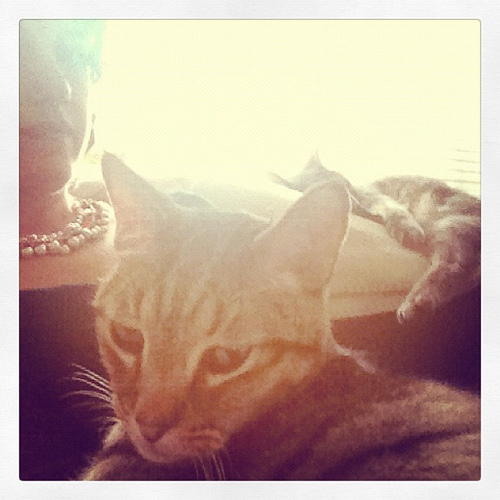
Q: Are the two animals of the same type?
A: Yes, all the animals are cats.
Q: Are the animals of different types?
A: No, all the animals are cats.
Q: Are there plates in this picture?
A: No, there are no plates.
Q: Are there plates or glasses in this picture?
A: No, there are no plates or glasses.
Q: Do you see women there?
A: Yes, there is a woman.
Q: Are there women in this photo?
A: Yes, there is a woman.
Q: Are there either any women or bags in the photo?
A: Yes, there is a woman.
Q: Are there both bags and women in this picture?
A: No, there is a woman but no bags.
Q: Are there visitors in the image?
A: No, there are no visitors.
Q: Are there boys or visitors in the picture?
A: No, there are no visitors or boys.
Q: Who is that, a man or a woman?
A: That is a woman.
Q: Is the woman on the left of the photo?
A: Yes, the woman is on the left of the image.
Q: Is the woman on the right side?
A: No, the woman is on the left of the image.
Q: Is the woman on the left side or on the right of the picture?
A: The woman is on the left of the image.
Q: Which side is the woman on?
A: The woman is on the left of the image.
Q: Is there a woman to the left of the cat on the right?
A: Yes, there is a woman to the left of the cat.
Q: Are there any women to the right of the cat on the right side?
A: No, the woman is to the left of the cat.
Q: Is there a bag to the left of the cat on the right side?
A: No, there is a woman to the left of the cat.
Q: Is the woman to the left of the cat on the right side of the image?
A: Yes, the woman is to the left of the cat.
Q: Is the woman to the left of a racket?
A: No, the woman is to the left of the cat.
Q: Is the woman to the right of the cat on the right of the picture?
A: No, the woman is to the left of the cat.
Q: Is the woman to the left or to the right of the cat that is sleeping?
A: The woman is to the left of the cat.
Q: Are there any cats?
A: Yes, there is a cat.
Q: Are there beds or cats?
A: Yes, there is a cat.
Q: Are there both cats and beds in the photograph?
A: No, there is a cat but no beds.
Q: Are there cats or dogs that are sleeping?
A: Yes, the cat is sleeping.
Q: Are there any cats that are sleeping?
A: Yes, there is a cat that is sleeping.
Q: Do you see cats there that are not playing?
A: Yes, there is a cat that is sleeping .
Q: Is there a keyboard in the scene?
A: No, there are no keyboards.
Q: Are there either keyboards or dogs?
A: No, there are no keyboards or dogs.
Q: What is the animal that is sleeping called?
A: The animal is a cat.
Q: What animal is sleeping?
A: The animal is a cat.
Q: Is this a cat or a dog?
A: This is a cat.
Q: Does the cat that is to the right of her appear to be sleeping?
A: Yes, the cat is sleeping.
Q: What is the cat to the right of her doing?
A: The cat is sleeping.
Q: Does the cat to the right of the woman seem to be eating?
A: No, the cat is sleeping.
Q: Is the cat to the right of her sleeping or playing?
A: The cat is sleeping.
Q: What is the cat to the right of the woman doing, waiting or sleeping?
A: The cat is sleeping.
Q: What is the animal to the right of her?
A: The animal is a cat.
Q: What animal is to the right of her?
A: The animal is a cat.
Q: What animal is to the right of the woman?
A: The animal is a cat.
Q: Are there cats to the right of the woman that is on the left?
A: Yes, there is a cat to the right of the woman.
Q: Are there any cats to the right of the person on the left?
A: Yes, there is a cat to the right of the woman.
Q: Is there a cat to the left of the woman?
A: No, the cat is to the right of the woman.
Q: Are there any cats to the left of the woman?
A: No, the cat is to the right of the woman.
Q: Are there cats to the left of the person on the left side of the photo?
A: No, the cat is to the right of the woman.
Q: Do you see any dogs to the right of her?
A: No, there is a cat to the right of the woman.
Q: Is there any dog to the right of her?
A: No, there is a cat to the right of the woman.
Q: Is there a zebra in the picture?
A: No, there are no zebras.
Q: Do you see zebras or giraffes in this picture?
A: No, there are no zebras or giraffes.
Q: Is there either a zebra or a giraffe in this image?
A: No, there are no zebras or giraffes.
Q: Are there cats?
A: Yes, there is a cat.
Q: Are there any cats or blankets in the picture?
A: Yes, there is a cat.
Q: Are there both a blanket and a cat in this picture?
A: No, there is a cat but no blankets.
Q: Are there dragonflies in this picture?
A: No, there are no dragonflies.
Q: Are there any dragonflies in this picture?
A: No, there are no dragonflies.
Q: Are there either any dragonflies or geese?
A: No, there are no dragonflies or geese.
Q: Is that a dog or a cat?
A: That is a cat.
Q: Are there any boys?
A: No, there are no boys.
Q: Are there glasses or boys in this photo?
A: No, there are no boys or glasses.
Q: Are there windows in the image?
A: Yes, there is a window.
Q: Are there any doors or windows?
A: Yes, there is a window.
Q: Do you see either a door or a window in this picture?
A: Yes, there is a window.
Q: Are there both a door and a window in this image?
A: No, there is a window but no doors.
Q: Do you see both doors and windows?
A: No, there is a window but no doors.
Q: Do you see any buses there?
A: No, there are no buses.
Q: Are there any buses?
A: No, there are no buses.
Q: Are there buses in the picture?
A: No, there are no buses.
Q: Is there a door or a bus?
A: No, there are no buses or doors.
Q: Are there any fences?
A: No, there are no fences.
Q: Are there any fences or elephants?
A: No, there are no fences or elephants.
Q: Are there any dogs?
A: No, there are no dogs.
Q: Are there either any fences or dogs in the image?
A: No, there are no dogs or fences.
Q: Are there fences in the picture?
A: No, there are no fences.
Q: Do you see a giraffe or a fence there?
A: No, there are no fences or giraffes.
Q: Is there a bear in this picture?
A: No, there are no bears.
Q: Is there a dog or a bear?
A: No, there are no bears or dogs.